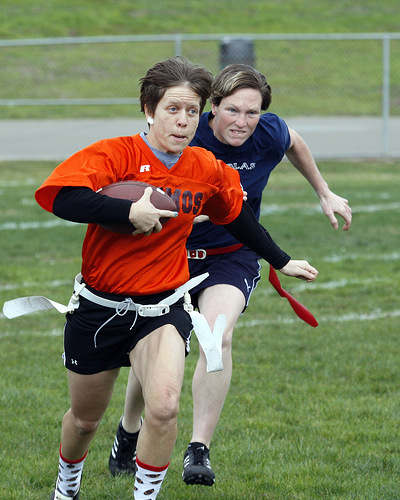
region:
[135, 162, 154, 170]
The white letter R on the kid's orange shirt.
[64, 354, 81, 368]
The white emblem on the player's black shorts in the orange shirt.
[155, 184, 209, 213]
The letters on the kid's orange shirt.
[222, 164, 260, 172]
The letters on the kid's blue shirt.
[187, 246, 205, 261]
The white belt fastener on the red belt.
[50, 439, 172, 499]
The red and white socks the kid in the orange shirt is wearing.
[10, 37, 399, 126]
The gray chain linked fence in the background.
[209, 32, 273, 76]
The black garbage can behind the chain linked fence.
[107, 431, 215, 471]
The white stripes on the player's cleats.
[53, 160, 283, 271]
The black sleeves on the arms of the player in the orange shirt.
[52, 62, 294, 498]
two people are running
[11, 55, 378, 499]
two people are running on green grass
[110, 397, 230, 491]
black shoes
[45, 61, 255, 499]
person wearing black shorts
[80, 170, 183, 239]
football is in photo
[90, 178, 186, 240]
football in photo is brown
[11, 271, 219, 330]
white belt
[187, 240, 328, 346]
red belt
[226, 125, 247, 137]
teeth is in photo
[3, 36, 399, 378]
fence is in the picture behind two people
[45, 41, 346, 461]
Two people playing football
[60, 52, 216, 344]
Football player in orange who has the ball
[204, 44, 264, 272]
Football player in blue pursuing the ball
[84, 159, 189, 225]
Football being carried by player in blue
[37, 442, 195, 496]
Red and white socks being worn by football player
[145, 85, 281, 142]
Faces of two football players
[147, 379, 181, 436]
Knee of football player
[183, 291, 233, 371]
White flag attached to player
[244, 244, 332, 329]
Red flag attached to player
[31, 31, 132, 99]
Gray fence next to grass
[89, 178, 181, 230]
The football in the player's hand.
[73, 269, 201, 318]
The white belt the player has around his waist.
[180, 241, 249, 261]
The red belt the player has around his waist.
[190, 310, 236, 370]
The white flag on the player's belt.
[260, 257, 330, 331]
The red flag on the player's waist.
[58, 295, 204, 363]
The black shorts the player is wearing.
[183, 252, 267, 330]
The blue shorts the player is wearing.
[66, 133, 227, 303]
The orange shirt the player is wearing.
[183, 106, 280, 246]
The blue shirt the player is wearing.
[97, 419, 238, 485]
The black and white cleats the player is wearing.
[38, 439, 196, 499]
Red and white socks on a man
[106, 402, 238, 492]
Black shoes on a man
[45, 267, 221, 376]
Black shorts on a man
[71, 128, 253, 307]
Orange jersey on a man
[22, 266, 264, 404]
White flags on a man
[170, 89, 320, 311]
Blue shirt on a man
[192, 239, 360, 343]
Red flag on a man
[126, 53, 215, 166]
Brown hair on a man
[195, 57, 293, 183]
Person with a grimace on their face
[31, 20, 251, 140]
Fence by a field